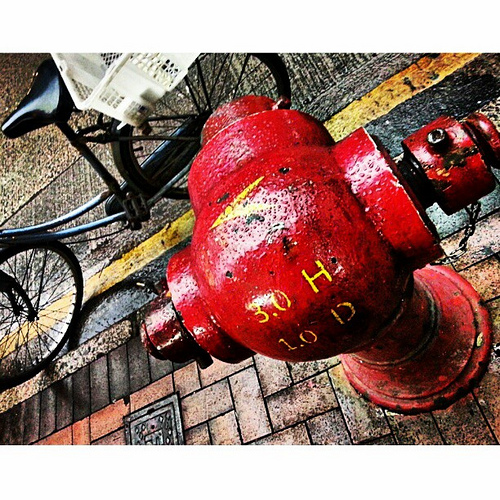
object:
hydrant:
[120, 92, 499, 410]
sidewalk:
[0, 211, 499, 446]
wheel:
[0, 238, 83, 394]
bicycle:
[0, 54, 293, 394]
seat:
[0, 58, 71, 142]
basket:
[47, 53, 203, 130]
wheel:
[119, 53, 291, 201]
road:
[0, 55, 499, 445]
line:
[0, 54, 483, 361]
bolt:
[427, 127, 449, 149]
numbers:
[299, 329, 319, 345]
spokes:
[231, 54, 251, 102]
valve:
[138, 280, 213, 370]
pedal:
[122, 193, 151, 223]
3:
[248, 303, 270, 325]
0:
[270, 289, 292, 312]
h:
[300, 260, 333, 294]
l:
[278, 338, 297, 353]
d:
[330, 301, 356, 326]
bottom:
[339, 265, 495, 415]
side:
[333, 111, 500, 273]